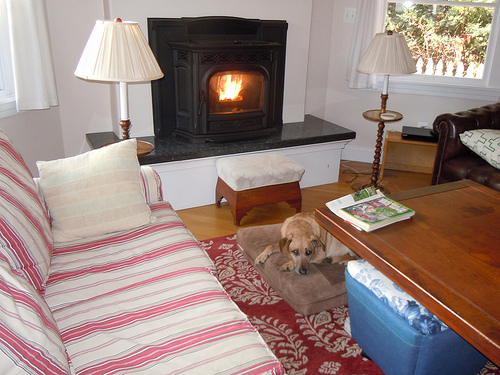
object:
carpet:
[198, 230, 500, 375]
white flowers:
[200, 235, 360, 375]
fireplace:
[147, 16, 289, 141]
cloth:
[0, 131, 282, 375]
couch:
[431, 102, 500, 192]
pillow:
[35, 138, 155, 249]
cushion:
[236, 224, 347, 316]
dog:
[254, 212, 362, 275]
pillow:
[236, 223, 348, 315]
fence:
[416, 56, 482, 78]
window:
[377, 0, 497, 82]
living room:
[0, 0, 500, 375]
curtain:
[3, 0, 59, 111]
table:
[315, 179, 500, 364]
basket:
[344, 260, 486, 375]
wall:
[0, 0, 499, 178]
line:
[113, 302, 169, 329]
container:
[345, 259, 488, 375]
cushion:
[0, 130, 285, 375]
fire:
[217, 73, 243, 100]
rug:
[200, 233, 500, 375]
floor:
[174, 160, 433, 242]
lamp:
[354, 31, 416, 193]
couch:
[0, 133, 285, 375]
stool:
[216, 153, 306, 226]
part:
[278, 305, 301, 349]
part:
[103, 273, 176, 341]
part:
[90, 227, 130, 266]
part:
[416, 278, 470, 302]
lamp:
[73, 18, 165, 156]